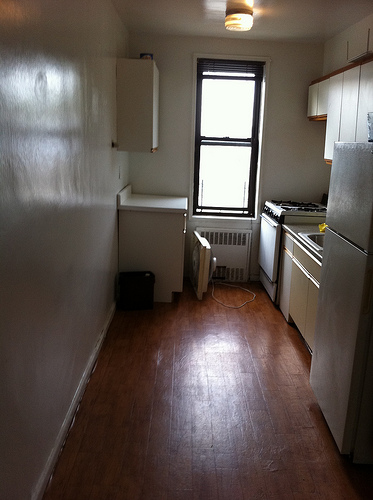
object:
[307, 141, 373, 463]
white fridge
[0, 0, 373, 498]
kitchen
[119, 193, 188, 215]
white counter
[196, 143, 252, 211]
window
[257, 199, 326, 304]
stove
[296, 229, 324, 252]
sink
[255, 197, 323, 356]
range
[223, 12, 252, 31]
yellow light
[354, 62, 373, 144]
cabinet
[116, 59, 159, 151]
cabinet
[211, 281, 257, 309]
wire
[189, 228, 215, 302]
fan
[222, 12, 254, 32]
light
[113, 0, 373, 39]
ceiling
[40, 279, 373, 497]
floor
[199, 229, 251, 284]
guard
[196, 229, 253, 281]
radiator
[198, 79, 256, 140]
window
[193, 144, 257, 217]
frame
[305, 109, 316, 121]
border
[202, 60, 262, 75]
blind